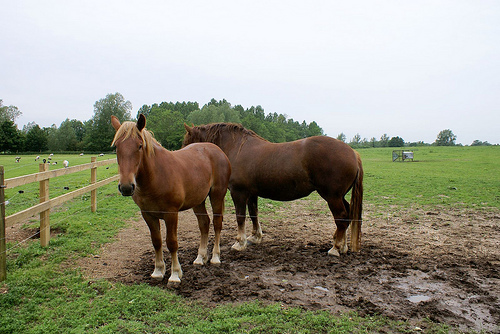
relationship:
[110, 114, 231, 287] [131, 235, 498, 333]
horse standing in mud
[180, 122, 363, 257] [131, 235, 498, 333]
horse standing in mud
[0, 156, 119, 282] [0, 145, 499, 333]
fence in field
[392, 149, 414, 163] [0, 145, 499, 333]
irrigation equipment in field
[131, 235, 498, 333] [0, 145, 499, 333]
mud in field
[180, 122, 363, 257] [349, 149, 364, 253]
horse has tail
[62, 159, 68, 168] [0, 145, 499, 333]
animal grazing in field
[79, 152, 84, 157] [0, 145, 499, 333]
animal grazing in field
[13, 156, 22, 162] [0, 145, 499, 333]
animal grazing in field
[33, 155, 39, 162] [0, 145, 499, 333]
animal grazing in field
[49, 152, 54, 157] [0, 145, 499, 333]
animal grazing in field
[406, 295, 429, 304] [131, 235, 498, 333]
puddle in mud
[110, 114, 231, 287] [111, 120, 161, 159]
horse with mane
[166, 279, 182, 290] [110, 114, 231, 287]
hoof of horse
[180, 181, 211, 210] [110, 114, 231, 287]
stomach of horse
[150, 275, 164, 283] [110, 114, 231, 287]
hoof of horse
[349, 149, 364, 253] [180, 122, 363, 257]
tail of horse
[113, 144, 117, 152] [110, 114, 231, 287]
eye of horse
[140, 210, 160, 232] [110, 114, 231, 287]
thigh of horse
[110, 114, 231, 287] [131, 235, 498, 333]
horse on mud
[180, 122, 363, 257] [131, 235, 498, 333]
horse on mud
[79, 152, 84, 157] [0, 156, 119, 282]
animal on or side of fence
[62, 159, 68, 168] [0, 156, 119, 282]
animal on or side of fence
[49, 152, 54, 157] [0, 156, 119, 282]
animal on or side of fence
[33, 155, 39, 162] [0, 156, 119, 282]
animal on or side of fence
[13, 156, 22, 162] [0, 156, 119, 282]
animal on or side of fence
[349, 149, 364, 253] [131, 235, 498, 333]
tail touching mud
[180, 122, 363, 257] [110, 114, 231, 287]
horse standing behind horse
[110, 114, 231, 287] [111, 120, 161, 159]
horse has mane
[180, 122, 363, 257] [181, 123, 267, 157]
horse has hair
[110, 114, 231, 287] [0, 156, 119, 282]
horse on side of fence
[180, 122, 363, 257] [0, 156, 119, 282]
horse on side of fence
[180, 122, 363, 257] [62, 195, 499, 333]
horse in corral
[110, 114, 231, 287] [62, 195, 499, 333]
horse in corral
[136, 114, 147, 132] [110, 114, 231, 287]
ear of horse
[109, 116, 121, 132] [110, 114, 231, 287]
ear of horse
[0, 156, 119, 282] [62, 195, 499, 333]
fence of corral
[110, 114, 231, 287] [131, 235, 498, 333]
horse stands in mud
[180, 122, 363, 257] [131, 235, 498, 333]
horse stands in mud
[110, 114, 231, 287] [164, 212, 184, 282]
horse has leg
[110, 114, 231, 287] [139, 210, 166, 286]
horse has leg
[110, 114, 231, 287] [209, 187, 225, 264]
horse has leg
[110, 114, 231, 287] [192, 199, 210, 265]
horse has leg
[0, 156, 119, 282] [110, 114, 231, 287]
fence beside horse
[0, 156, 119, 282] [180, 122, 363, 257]
fence beside horse